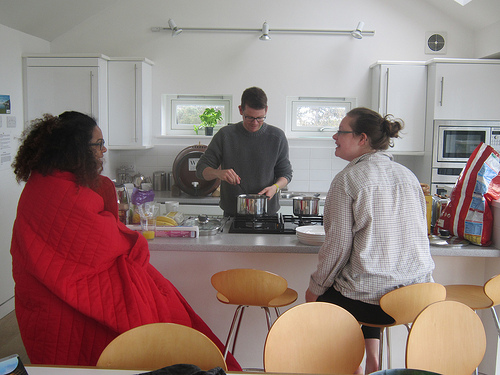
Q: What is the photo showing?
A: It is showing a kitchen.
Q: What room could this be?
A: It is a kitchen.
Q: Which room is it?
A: It is a kitchen.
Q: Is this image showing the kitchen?
A: Yes, it is showing the kitchen.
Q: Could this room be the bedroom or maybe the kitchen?
A: It is the kitchen.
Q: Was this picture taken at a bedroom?
A: No, the picture was taken in a kitchen.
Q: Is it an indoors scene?
A: Yes, it is indoors.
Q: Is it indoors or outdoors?
A: It is indoors.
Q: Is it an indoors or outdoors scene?
A: It is indoors.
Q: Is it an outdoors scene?
A: No, it is indoors.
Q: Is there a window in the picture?
A: Yes, there is a window.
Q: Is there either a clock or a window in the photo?
A: Yes, there is a window.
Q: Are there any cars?
A: No, there are no cars.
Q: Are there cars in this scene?
A: No, there are no cars.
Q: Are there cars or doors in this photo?
A: No, there are no cars or doors.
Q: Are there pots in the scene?
A: Yes, there is a pot.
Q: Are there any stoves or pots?
A: Yes, there is a pot.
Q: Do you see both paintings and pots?
A: No, there is a pot but no paintings.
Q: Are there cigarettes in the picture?
A: No, there are no cigarettes.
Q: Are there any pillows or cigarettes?
A: No, there are no cigarettes or pillows.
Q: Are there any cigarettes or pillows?
A: No, there are no cigarettes or pillows.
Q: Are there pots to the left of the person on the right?
A: Yes, there is a pot to the left of the person.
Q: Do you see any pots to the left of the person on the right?
A: Yes, there is a pot to the left of the person.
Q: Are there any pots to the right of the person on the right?
A: No, the pot is to the left of the person.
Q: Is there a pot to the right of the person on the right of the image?
A: No, the pot is to the left of the person.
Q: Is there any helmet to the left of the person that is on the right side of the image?
A: No, there is a pot to the left of the person.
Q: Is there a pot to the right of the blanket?
A: Yes, there is a pot to the right of the blanket.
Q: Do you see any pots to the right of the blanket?
A: Yes, there is a pot to the right of the blanket.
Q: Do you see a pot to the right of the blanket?
A: Yes, there is a pot to the right of the blanket.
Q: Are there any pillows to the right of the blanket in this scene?
A: No, there is a pot to the right of the blanket.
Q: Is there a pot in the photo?
A: Yes, there is a pot.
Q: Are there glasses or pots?
A: Yes, there is a pot.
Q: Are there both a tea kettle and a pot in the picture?
A: No, there is a pot but no tea kettles.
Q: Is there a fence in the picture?
A: No, there are no fences.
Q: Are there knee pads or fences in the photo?
A: No, there are no fences or knee pads.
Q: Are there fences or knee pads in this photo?
A: No, there are no fences or knee pads.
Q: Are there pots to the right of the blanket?
A: Yes, there is a pot to the right of the blanket.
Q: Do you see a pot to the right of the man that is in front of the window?
A: Yes, there is a pot to the right of the man.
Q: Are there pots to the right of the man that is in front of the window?
A: Yes, there is a pot to the right of the man.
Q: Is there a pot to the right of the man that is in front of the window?
A: Yes, there is a pot to the right of the man.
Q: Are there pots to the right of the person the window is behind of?
A: Yes, there is a pot to the right of the man.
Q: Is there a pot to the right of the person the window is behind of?
A: Yes, there is a pot to the right of the man.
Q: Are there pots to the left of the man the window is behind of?
A: No, the pot is to the right of the man.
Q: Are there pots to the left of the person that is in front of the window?
A: No, the pot is to the right of the man.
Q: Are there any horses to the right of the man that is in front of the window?
A: No, there is a pot to the right of the man.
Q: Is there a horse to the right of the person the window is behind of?
A: No, there is a pot to the right of the man.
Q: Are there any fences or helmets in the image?
A: No, there are no fences or helmets.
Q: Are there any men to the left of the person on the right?
A: Yes, there is a man to the left of the person.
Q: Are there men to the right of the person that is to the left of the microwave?
A: No, the man is to the left of the person.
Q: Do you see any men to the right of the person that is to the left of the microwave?
A: No, the man is to the left of the person.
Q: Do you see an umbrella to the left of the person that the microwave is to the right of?
A: No, there is a man to the left of the person.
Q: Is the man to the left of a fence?
A: No, the man is to the left of a person.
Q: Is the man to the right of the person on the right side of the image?
A: No, the man is to the left of the person.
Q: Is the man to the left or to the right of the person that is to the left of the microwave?
A: The man is to the left of the person.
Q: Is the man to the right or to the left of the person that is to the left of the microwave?
A: The man is to the left of the person.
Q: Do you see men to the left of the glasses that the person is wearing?
A: Yes, there is a man to the left of the glasses.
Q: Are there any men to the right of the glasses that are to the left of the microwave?
A: No, the man is to the left of the glasses.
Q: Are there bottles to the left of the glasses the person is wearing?
A: No, there is a man to the left of the glasses.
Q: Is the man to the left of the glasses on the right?
A: Yes, the man is to the left of the glasses.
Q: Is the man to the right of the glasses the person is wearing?
A: No, the man is to the left of the glasses.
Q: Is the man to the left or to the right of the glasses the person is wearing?
A: The man is to the left of the glasses.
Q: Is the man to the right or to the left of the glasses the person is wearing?
A: The man is to the left of the glasses.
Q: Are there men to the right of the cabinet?
A: Yes, there is a man to the right of the cabinet.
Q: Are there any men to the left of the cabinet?
A: No, the man is to the right of the cabinet.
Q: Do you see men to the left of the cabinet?
A: No, the man is to the right of the cabinet.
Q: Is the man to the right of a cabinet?
A: Yes, the man is to the right of a cabinet.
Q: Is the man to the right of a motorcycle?
A: No, the man is to the right of a cabinet.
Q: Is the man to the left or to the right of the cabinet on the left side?
A: The man is to the right of the cabinet.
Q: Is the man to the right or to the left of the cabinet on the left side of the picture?
A: The man is to the right of the cabinet.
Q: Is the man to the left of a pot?
A: Yes, the man is to the left of a pot.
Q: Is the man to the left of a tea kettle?
A: No, the man is to the left of a pot.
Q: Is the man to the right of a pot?
A: No, the man is to the left of a pot.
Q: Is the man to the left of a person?
A: No, the man is to the right of a person.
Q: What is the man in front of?
A: The man is in front of the window.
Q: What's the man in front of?
A: The man is in front of the window.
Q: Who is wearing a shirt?
A: The man is wearing a shirt.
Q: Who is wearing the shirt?
A: The man is wearing a shirt.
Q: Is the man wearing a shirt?
A: Yes, the man is wearing a shirt.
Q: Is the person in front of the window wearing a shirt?
A: Yes, the man is wearing a shirt.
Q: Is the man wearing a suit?
A: No, the man is wearing a shirt.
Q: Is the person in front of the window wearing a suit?
A: No, the man is wearing a shirt.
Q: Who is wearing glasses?
A: The man is wearing glasses.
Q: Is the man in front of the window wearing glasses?
A: Yes, the man is wearing glasses.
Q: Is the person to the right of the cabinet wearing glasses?
A: Yes, the man is wearing glasses.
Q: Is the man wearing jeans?
A: No, the man is wearing glasses.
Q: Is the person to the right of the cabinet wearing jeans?
A: No, the man is wearing glasses.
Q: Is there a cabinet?
A: Yes, there is a cabinet.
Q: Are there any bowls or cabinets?
A: Yes, there is a cabinet.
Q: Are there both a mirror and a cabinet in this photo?
A: No, there is a cabinet but no mirrors.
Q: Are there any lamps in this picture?
A: No, there are no lamps.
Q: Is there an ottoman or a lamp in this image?
A: No, there are no lamps or ottomen.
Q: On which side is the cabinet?
A: The cabinet is on the left of the image.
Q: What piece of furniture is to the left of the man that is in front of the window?
A: The piece of furniture is a cabinet.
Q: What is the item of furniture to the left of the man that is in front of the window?
A: The piece of furniture is a cabinet.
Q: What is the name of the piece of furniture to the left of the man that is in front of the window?
A: The piece of furniture is a cabinet.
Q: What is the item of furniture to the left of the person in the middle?
A: The piece of furniture is a cabinet.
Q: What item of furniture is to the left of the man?
A: The piece of furniture is a cabinet.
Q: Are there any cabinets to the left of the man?
A: Yes, there is a cabinet to the left of the man.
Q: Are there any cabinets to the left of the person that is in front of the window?
A: Yes, there is a cabinet to the left of the man.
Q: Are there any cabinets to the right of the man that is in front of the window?
A: No, the cabinet is to the left of the man.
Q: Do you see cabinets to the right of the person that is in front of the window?
A: No, the cabinet is to the left of the man.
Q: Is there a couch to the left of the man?
A: No, there is a cabinet to the left of the man.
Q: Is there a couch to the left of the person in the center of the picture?
A: No, there is a cabinet to the left of the man.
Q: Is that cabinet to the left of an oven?
A: No, the cabinet is to the left of the man.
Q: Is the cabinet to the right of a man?
A: No, the cabinet is to the left of a man.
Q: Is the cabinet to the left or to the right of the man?
A: The cabinet is to the left of the man.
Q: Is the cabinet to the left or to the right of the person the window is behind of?
A: The cabinet is to the left of the man.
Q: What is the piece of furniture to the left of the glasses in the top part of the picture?
A: The piece of furniture is a cabinet.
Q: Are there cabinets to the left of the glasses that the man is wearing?
A: Yes, there is a cabinet to the left of the glasses.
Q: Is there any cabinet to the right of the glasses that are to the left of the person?
A: No, the cabinet is to the left of the glasses.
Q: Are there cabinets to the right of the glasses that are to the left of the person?
A: No, the cabinet is to the left of the glasses.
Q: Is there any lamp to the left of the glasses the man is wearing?
A: No, there is a cabinet to the left of the glasses.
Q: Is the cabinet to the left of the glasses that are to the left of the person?
A: Yes, the cabinet is to the left of the glasses.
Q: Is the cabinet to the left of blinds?
A: No, the cabinet is to the left of the glasses.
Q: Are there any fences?
A: No, there are no fences.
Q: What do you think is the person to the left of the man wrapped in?
A: The person is wrapped in a blanket.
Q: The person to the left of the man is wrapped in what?
A: The person is wrapped in a blanket.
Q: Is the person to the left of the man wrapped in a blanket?
A: Yes, the person is wrapped in a blanket.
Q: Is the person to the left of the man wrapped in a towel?
A: No, the person is wrapped in a blanket.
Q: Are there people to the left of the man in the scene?
A: Yes, there is a person to the left of the man.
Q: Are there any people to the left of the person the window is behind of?
A: Yes, there is a person to the left of the man.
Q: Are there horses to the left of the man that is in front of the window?
A: No, there is a person to the left of the man.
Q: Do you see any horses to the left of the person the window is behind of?
A: No, there is a person to the left of the man.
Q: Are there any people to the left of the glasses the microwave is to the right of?
A: Yes, there is a person to the left of the glasses.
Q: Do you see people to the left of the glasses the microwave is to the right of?
A: Yes, there is a person to the left of the glasses.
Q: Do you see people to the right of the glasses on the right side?
A: No, the person is to the left of the glasses.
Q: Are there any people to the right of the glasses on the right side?
A: No, the person is to the left of the glasses.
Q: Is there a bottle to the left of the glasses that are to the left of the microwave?
A: No, there is a person to the left of the glasses.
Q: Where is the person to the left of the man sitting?
A: The person is sitting in the kitchen.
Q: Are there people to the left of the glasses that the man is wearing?
A: Yes, there is a person to the left of the glasses.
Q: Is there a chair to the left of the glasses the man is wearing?
A: No, there is a person to the left of the glasses.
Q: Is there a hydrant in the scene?
A: No, there are no fire hydrants.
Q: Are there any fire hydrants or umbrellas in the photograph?
A: No, there are no fire hydrants or umbrellas.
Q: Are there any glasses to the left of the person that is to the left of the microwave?
A: Yes, there are glasses to the left of the person.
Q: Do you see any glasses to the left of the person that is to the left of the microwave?
A: Yes, there are glasses to the left of the person.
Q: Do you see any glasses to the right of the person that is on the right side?
A: No, the glasses are to the left of the person.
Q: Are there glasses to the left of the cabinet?
A: No, the glasses are to the right of the cabinet.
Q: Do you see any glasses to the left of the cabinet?
A: No, the glasses are to the right of the cabinet.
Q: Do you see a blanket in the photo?
A: Yes, there is a blanket.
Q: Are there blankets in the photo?
A: Yes, there is a blanket.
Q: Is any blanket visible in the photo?
A: Yes, there is a blanket.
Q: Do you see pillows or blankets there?
A: Yes, there is a blanket.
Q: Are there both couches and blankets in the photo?
A: No, there is a blanket but no couches.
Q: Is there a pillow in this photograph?
A: No, there are no pillows.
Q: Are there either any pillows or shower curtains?
A: No, there are no pillows or shower curtains.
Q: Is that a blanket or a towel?
A: That is a blanket.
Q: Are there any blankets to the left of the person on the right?
A: Yes, there is a blanket to the left of the person.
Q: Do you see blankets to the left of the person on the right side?
A: Yes, there is a blanket to the left of the person.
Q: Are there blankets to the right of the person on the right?
A: No, the blanket is to the left of the person.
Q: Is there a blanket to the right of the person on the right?
A: No, the blanket is to the left of the person.